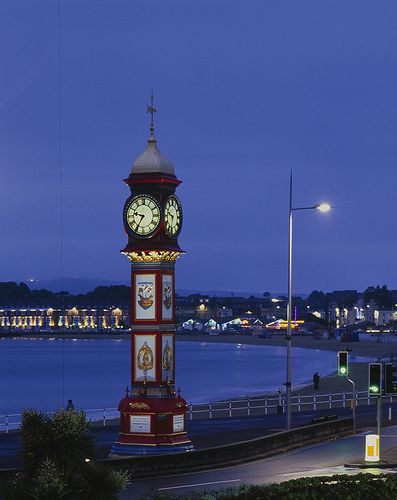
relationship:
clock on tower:
[123, 191, 176, 237] [108, 87, 207, 455]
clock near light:
[123, 191, 176, 237] [259, 151, 343, 377]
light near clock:
[259, 151, 343, 377] [123, 191, 176, 237]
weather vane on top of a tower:
[136, 91, 176, 141] [108, 87, 207, 455]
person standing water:
[62, 397, 77, 410] [3, 332, 327, 425]